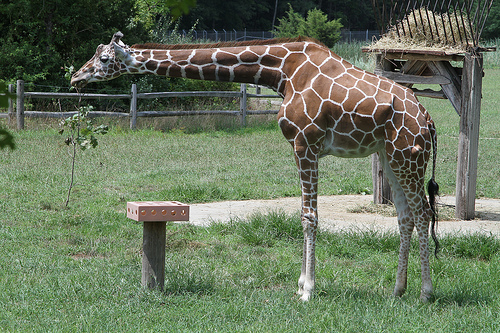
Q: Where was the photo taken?
A: At a zoo.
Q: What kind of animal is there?
A: A giraffe.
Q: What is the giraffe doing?
A: Eating.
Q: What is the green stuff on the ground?
A: Grass.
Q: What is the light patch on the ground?
A: Dirt.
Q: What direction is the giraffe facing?
A: Left.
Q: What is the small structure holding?
A: Hay.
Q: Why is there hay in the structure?
A: For feeding giraffes.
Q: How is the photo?
A: Clear.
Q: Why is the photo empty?
A: There is no one.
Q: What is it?
A: A giraffe.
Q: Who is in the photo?
A: Nobody.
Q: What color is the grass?
A: Green.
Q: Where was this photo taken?
A: At the zoo.